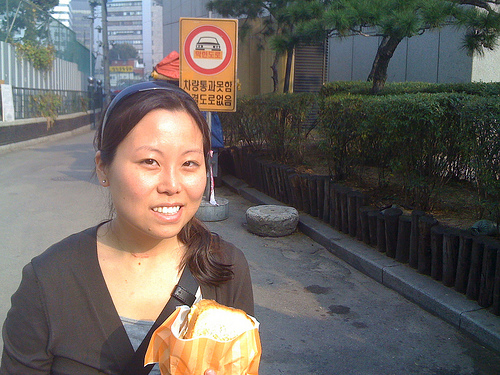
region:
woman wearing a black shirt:
[5, 210, 235, 372]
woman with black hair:
[81, 81, 201, 150]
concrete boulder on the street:
[241, 200, 297, 231]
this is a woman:
[11, 43, 322, 364]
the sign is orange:
[170, 3, 247, 108]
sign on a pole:
[152, 9, 259, 229]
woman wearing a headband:
[94, 59, 219, 228]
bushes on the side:
[235, 37, 482, 220]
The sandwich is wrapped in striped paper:
[134, 314, 249, 373]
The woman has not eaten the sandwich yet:
[139, 295, 269, 363]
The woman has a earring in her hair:
[95, 173, 119, 190]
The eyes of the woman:
[129, 152, 223, 180]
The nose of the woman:
[152, 164, 186, 196]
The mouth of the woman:
[145, 200, 193, 222]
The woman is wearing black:
[11, 220, 263, 365]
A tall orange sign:
[174, 15, 239, 112]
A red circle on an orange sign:
[182, 24, 229, 74]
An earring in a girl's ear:
[94, 173, 111, 188]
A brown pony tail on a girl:
[177, 223, 234, 283]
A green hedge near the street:
[245, 82, 499, 227]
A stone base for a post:
[242, 202, 297, 237]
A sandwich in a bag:
[176, 302, 257, 338]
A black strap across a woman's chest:
[124, 253, 204, 373]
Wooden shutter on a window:
[295, 40, 326, 86]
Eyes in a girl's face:
[139, 154, 201, 169]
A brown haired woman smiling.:
[0, 79, 254, 373]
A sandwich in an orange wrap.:
[186, 300, 253, 342]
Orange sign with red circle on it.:
[178, 16, 238, 111]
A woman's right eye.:
[140, 154, 160, 168]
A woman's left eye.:
[180, 160, 197, 167]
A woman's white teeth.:
[148, 204, 182, 216]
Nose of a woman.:
[156, 162, 181, 197]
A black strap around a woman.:
[116, 258, 201, 374]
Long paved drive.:
[0, 127, 491, 372]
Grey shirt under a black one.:
[118, 314, 163, 373]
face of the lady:
[96, 103, 238, 223]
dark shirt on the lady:
[16, 226, 131, 351]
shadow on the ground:
[287, 264, 353, 327]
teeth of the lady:
[153, 190, 190, 218]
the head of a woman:
[92, 91, 220, 229]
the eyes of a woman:
[122, 142, 209, 189]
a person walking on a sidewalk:
[3, 89, 265, 359]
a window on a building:
[137, 10, 143, 17]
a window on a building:
[105, 13, 111, 17]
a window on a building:
[111, 10, 119, 13]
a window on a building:
[125, 13, 135, 18]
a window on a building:
[108, 30, 109, 39]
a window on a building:
[118, 30, 125, 36]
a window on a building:
[131, 30, 137, 37]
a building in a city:
[91, 0, 161, 95]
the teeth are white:
[152, 205, 181, 215]